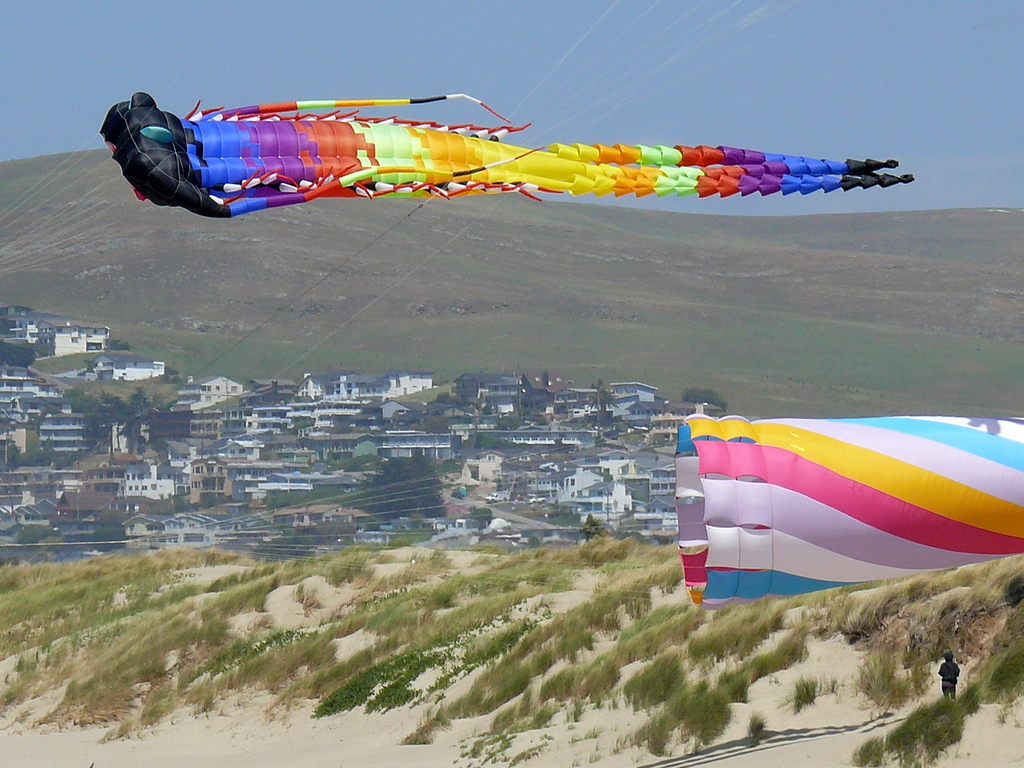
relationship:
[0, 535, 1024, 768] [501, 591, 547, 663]
grass green and yellow grass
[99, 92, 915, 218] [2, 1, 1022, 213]
wind sock flying in sky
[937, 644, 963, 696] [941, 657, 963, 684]
man wearing shirt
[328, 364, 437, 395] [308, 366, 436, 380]
house with roof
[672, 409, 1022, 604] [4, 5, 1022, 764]
balloon in air